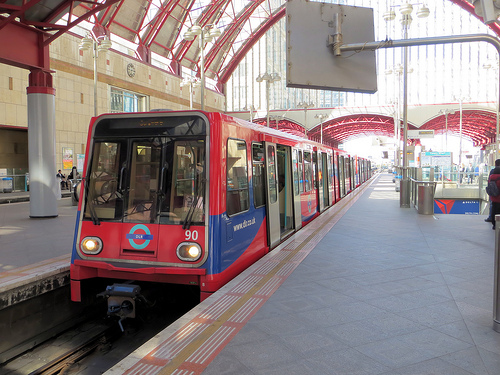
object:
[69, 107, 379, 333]
train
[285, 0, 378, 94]
sign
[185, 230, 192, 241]
9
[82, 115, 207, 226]
windshield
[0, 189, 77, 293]
walkway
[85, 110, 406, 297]
bus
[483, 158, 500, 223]
person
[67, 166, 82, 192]
person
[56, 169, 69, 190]
person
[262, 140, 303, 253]
door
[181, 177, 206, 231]
windshield wiper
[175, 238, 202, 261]
headlight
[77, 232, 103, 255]
headlight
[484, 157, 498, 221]
passenger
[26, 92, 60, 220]
white pole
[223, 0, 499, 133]
wall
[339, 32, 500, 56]
pole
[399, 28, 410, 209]
pole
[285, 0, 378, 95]
board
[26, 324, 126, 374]
track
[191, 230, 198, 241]
0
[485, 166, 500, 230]
person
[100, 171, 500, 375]
walkway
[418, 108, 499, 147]
archways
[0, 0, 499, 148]
ceiling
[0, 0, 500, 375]
train station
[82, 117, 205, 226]
window